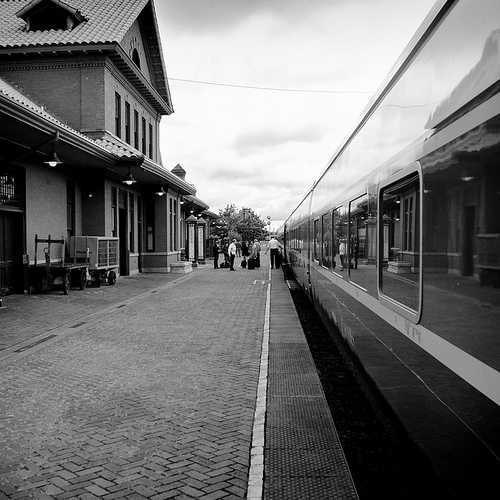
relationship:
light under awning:
[42, 155, 64, 172] [1, 120, 235, 237]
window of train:
[373, 187, 428, 315] [268, 185, 485, 442]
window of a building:
[141, 196, 160, 254] [1, 0, 251, 302]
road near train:
[1, 230, 358, 499] [273, 2, 497, 498]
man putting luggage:
[263, 235, 285, 269] [238, 257, 258, 267]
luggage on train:
[238, 257, 258, 267] [273, 0, 499, 435]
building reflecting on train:
[0, 1, 210, 306] [273, 2, 497, 498]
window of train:
[321, 211, 331, 268] [273, 2, 497, 498]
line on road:
[243, 247, 273, 498] [1, 230, 358, 499]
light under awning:
[42, 155, 64, 168] [1, 82, 144, 175]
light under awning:
[151, 185, 166, 200] [1, 92, 208, 218]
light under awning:
[121, 173, 139, 185] [1, 92, 208, 218]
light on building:
[121, 173, 139, 185] [0, 1, 210, 306]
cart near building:
[68, 235, 120, 284] [0, 1, 210, 306]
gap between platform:
[281, 265, 449, 499] [2, 249, 362, 499]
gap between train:
[281, 265, 449, 499] [273, 2, 497, 498]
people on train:
[212, 236, 283, 269] [273, 2, 497, 498]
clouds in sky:
[167, 0, 412, 211] [150, 0, 441, 235]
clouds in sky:
[208, 143, 335, 191] [150, 0, 441, 235]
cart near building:
[47, 235, 120, 295] [0, 1, 210, 306]